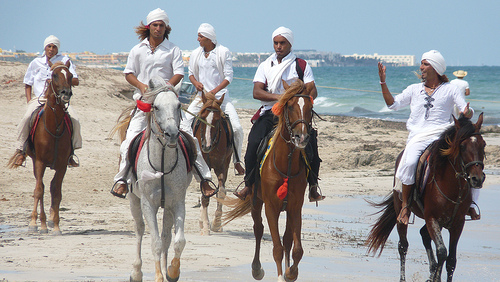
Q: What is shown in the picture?
A: A beach.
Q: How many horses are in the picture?
A: Five.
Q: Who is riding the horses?
A: Five men.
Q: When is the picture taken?
A: In the daytime.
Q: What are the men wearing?
A: Turbans.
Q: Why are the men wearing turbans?
A: It's their custom.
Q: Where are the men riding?
A: On the beach.